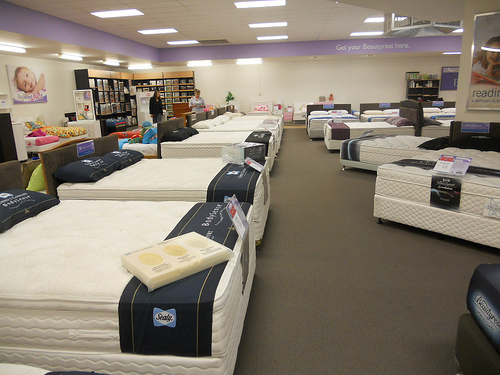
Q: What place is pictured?
A: It is a store.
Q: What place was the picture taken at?
A: It was taken at the store.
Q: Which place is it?
A: It is a store.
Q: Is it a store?
A: Yes, it is a store.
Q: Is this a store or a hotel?
A: It is a store.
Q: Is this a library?
A: No, it is a store.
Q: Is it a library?
A: No, it is a store.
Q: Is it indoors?
A: Yes, it is indoors.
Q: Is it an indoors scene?
A: Yes, it is indoors.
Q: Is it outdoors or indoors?
A: It is indoors.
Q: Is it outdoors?
A: No, it is indoors.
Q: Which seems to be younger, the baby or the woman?
A: The baby is younger than the woman.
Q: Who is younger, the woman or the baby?
A: The baby is younger than the woman.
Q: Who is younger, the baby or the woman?
A: The baby is younger than the woman.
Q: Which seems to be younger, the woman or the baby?
A: The baby is younger than the woman.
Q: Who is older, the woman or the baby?
A: The woman is older than the baby.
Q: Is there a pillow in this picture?
A: Yes, there are pillows.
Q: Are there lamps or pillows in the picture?
A: Yes, there are pillows.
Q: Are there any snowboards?
A: No, there are no snowboards.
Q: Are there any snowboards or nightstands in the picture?
A: No, there are no snowboards or nightstands.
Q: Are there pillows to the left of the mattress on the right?
A: Yes, there are pillows to the left of the mattress.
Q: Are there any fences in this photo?
A: No, there are no fences.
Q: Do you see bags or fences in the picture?
A: No, there are no fences or bags.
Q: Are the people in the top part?
A: Yes, the people are in the top of the image.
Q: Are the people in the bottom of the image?
A: No, the people are in the top of the image.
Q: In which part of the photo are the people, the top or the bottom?
A: The people are in the top of the image.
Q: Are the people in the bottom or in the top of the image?
A: The people are in the top of the image.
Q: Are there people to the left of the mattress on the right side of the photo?
A: Yes, there are people to the left of the mattress.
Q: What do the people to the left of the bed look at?
A: The people look at the mattresses.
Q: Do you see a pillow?
A: Yes, there are pillows.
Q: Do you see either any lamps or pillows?
A: Yes, there are pillows.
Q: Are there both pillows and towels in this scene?
A: No, there are pillows but no towels.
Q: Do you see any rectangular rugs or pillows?
A: Yes, there are rectangular pillows.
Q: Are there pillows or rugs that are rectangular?
A: Yes, the pillows are rectangular.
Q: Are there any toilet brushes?
A: No, there are no toilet brushes.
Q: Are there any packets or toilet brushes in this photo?
A: No, there are no toilet brushes or packets.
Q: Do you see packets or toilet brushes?
A: No, there are no toilet brushes or packets.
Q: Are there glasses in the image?
A: No, there are no glasses.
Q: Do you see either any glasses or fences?
A: No, there are no glasses or fences.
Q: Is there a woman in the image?
A: Yes, there is a woman.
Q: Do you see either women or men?
A: Yes, there is a woman.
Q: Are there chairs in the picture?
A: No, there are no chairs.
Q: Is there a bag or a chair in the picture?
A: No, there are no chairs or bags.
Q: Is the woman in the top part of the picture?
A: Yes, the woman is in the top of the image.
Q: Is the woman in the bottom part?
A: No, the woman is in the top of the image.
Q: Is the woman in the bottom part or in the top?
A: The woman is in the top of the image.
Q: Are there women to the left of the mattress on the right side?
A: Yes, there is a woman to the left of the mattress.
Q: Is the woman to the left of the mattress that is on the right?
A: Yes, the woman is to the left of the mattress.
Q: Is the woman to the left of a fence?
A: No, the woman is to the left of the mattress.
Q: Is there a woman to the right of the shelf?
A: Yes, there is a woman to the right of the shelf.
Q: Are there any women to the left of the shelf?
A: No, the woman is to the right of the shelf.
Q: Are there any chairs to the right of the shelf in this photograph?
A: No, there is a woman to the right of the shelf.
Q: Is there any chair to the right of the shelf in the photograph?
A: No, there is a woman to the right of the shelf.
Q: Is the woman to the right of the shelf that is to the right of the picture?
A: Yes, the woman is to the right of the shelf.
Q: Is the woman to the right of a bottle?
A: No, the woman is to the right of the shelf.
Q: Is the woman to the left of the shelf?
A: No, the woman is to the right of the shelf.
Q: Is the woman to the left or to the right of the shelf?
A: The woman is to the right of the shelf.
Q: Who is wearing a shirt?
A: The woman is wearing a shirt.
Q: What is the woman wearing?
A: The woman is wearing a shirt.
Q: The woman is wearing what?
A: The woman is wearing a shirt.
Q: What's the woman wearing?
A: The woman is wearing a shirt.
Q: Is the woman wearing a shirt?
A: Yes, the woman is wearing a shirt.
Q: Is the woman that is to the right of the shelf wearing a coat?
A: No, the woman is wearing a shirt.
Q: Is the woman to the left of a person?
A: No, the woman is to the right of a person.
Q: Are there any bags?
A: No, there are no bags.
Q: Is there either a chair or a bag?
A: No, there are no bags or chairs.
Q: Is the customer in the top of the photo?
A: Yes, the customer is in the top of the image.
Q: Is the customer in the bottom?
A: No, the customer is in the top of the image.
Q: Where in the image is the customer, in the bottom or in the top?
A: The customer is in the top of the image.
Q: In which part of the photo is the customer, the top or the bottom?
A: The customer is in the top of the image.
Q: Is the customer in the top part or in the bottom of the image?
A: The customer is in the top of the image.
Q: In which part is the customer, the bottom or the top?
A: The customer is in the top of the image.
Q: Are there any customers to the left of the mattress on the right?
A: Yes, there is a customer to the left of the mattress.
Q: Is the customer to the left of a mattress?
A: Yes, the customer is to the left of a mattress.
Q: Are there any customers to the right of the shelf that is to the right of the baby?
A: Yes, there is a customer to the right of the shelf.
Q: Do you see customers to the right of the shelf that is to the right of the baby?
A: Yes, there is a customer to the right of the shelf.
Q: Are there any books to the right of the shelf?
A: No, there is a customer to the right of the shelf.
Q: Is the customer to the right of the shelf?
A: Yes, the customer is to the right of the shelf.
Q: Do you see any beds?
A: Yes, there is a bed.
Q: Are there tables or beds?
A: Yes, there is a bed.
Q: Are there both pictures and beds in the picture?
A: Yes, there are both a bed and a picture.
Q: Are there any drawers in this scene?
A: No, there are no drawers.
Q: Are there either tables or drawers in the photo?
A: No, there are no drawers or tables.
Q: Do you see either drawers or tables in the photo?
A: No, there are no drawers or tables.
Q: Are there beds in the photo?
A: Yes, there is a bed.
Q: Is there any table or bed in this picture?
A: Yes, there is a bed.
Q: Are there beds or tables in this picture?
A: Yes, there is a bed.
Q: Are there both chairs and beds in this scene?
A: No, there is a bed but no chairs.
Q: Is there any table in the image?
A: No, there are no tables.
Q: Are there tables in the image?
A: No, there are no tables.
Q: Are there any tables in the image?
A: No, there are no tables.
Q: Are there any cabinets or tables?
A: No, there are no tables or cabinets.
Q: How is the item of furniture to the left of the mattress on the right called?
A: The piece of furniture is a bed.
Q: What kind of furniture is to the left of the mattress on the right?
A: The piece of furniture is a bed.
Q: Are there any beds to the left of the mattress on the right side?
A: Yes, there is a bed to the left of the mattress.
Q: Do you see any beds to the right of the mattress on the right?
A: No, the bed is to the left of the mattress.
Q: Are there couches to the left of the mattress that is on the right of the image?
A: No, there is a bed to the left of the mattress.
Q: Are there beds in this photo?
A: Yes, there is a bed.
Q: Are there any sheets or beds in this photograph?
A: Yes, there is a bed.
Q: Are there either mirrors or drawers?
A: No, there are no drawers or mirrors.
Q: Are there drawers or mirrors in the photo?
A: No, there are no drawers or mirrors.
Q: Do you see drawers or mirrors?
A: No, there are no drawers or mirrors.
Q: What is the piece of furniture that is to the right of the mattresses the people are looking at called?
A: The piece of furniture is a bed.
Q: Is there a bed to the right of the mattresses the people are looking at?
A: Yes, there is a bed to the right of the mattresses.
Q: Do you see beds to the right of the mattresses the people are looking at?
A: Yes, there is a bed to the right of the mattresses.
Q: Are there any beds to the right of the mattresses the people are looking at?
A: Yes, there is a bed to the right of the mattresses.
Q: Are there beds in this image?
A: Yes, there is a bed.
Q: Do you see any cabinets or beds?
A: Yes, there is a bed.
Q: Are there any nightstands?
A: No, there are no nightstands.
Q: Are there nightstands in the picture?
A: No, there are no nightstands.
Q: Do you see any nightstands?
A: No, there are no nightstands.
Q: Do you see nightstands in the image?
A: No, there are no nightstands.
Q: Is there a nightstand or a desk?
A: No, there are no nightstands or desks.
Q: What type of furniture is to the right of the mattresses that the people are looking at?
A: The piece of furniture is a bed.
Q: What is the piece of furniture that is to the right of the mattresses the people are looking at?
A: The piece of furniture is a bed.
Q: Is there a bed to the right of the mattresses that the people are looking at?
A: Yes, there is a bed to the right of the mattresses.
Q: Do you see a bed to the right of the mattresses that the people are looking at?
A: Yes, there is a bed to the right of the mattresses.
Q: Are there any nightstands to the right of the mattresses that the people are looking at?
A: No, there is a bed to the right of the mattresses.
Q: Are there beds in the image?
A: Yes, there is a bed.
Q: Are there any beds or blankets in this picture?
A: Yes, there is a bed.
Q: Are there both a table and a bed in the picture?
A: No, there is a bed but no tables.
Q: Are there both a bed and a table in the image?
A: No, there is a bed but no tables.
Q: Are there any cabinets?
A: No, there are no cabinets.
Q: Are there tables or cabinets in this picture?
A: No, there are no cabinets or tables.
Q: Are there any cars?
A: No, there are no cars.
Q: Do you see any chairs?
A: No, there are no chairs.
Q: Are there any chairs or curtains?
A: No, there are no chairs or curtains.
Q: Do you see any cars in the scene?
A: No, there are no cars.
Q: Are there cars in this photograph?
A: No, there are no cars.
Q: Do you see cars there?
A: No, there are no cars.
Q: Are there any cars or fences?
A: No, there are no cars or fences.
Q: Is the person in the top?
A: Yes, the person is in the top of the image.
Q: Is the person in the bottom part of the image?
A: No, the person is in the top of the image.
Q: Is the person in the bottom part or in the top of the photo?
A: The person is in the top of the image.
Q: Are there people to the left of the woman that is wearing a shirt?
A: Yes, there is a person to the left of the woman.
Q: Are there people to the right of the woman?
A: No, the person is to the left of the woman.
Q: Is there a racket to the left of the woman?
A: No, there is a person to the left of the woman.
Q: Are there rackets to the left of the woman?
A: No, there is a person to the left of the woman.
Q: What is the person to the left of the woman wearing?
A: The person is wearing a shirt.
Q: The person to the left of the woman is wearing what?
A: The person is wearing a shirt.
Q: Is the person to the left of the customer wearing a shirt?
A: Yes, the person is wearing a shirt.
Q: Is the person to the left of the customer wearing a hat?
A: No, the person is wearing a shirt.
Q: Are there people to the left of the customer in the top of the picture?
A: Yes, there is a person to the left of the customer.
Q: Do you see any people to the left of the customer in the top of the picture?
A: Yes, there is a person to the left of the customer.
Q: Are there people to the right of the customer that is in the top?
A: No, the person is to the left of the customer.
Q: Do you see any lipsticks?
A: No, there are no lipsticks.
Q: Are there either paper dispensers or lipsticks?
A: No, there are no lipsticks or paper dispensers.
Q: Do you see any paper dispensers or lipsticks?
A: No, there are no lipsticks or paper dispensers.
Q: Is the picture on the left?
A: Yes, the picture is on the left of the image.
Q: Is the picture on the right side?
A: No, the picture is on the left of the image.